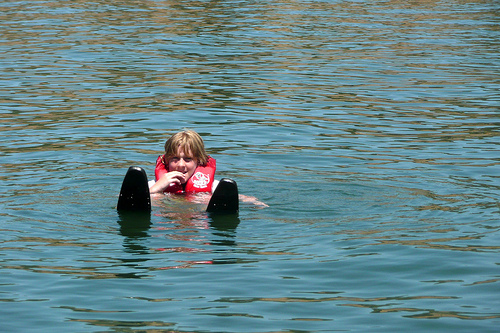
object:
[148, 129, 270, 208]
boy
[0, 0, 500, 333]
water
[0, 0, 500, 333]
lake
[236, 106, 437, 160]
ripple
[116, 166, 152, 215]
fins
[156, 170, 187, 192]
hand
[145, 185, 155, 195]
arm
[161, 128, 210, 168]
hair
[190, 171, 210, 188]
logo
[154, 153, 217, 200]
life preserver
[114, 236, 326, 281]
reflection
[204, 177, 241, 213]
shoes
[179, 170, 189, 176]
mouth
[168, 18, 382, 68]
sun